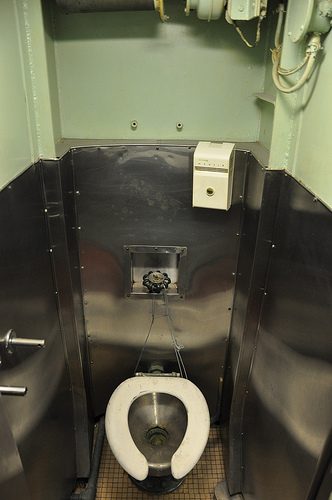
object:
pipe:
[80, 415, 104, 500]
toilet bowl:
[127, 392, 188, 477]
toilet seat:
[104, 376, 211, 482]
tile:
[102, 477, 107, 483]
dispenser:
[192, 140, 236, 211]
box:
[192, 141, 237, 212]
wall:
[0, 138, 332, 500]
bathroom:
[0, 0, 332, 500]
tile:
[206, 451, 210, 455]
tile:
[207, 469, 212, 474]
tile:
[104, 472, 109, 477]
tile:
[197, 474, 202, 479]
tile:
[194, 493, 200, 499]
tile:
[111, 492, 116, 497]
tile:
[203, 478, 208, 484]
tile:
[108, 472, 113, 478]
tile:
[210, 455, 215, 460]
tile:
[217, 464, 222, 468]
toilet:
[104, 364, 210, 495]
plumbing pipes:
[271, 3, 323, 93]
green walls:
[0, 0, 332, 212]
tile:
[105, 459, 110, 463]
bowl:
[127, 391, 188, 468]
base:
[128, 476, 185, 496]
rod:
[9, 337, 46, 350]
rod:
[0, 385, 28, 397]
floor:
[70, 423, 225, 500]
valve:
[142, 270, 171, 293]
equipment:
[133, 270, 188, 380]